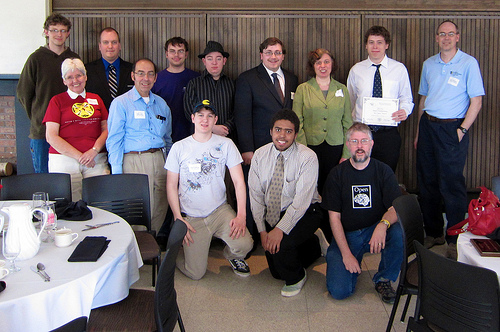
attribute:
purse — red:
[444, 183, 497, 235]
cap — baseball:
[185, 95, 225, 118]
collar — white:
[68, 87, 86, 100]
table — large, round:
[25, 200, 166, 308]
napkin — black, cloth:
[63, 233, 110, 265]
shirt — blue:
[98, 87, 155, 147]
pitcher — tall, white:
[2, 193, 45, 270]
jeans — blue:
[330, 212, 410, 302]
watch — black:
[445, 102, 480, 169]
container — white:
[2, 202, 47, 258]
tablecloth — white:
[1, 187, 143, 329]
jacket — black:
[77, 54, 134, 99]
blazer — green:
[291, 74, 353, 145]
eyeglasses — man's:
[137, 69, 155, 77]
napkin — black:
[68, 233, 110, 268]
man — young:
[240, 110, 317, 292]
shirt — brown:
[247, 139, 315, 232]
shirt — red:
[16, 83, 130, 163]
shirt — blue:
[416, 49, 486, 114]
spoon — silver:
[36, 259, 53, 281]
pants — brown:
[121, 149, 170, 229]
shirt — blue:
[99, 88, 181, 173]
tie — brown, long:
[265, 152, 283, 227]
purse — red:
[474, 195, 489, 251]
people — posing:
[411, 20, 485, 263]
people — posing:
[344, 23, 411, 168]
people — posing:
[323, 120, 400, 304]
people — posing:
[246, 105, 325, 297]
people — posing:
[290, 47, 355, 195]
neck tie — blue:
[371, 64, 381, 98]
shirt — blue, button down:
[105, 86, 172, 173]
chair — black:
[403, 253, 498, 325]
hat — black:
[181, 30, 231, 70]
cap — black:
[185, 81, 232, 123]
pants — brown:
[178, 208, 256, 275]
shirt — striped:
[188, 73, 230, 119]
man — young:
[183, 38, 239, 129]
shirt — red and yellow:
[38, 91, 108, 160]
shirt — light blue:
[423, 50, 484, 121]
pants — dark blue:
[412, 108, 466, 221]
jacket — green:
[291, 81, 351, 139]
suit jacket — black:
[84, 57, 143, 99]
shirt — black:
[324, 160, 406, 229]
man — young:
[163, 96, 257, 285]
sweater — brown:
[17, 44, 68, 116]